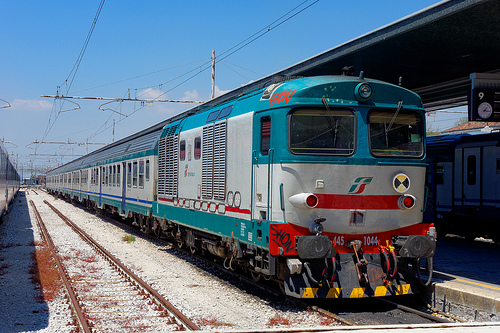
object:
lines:
[66, 45, 132, 124]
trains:
[172, 105, 413, 290]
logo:
[345, 171, 376, 206]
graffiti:
[268, 226, 302, 261]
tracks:
[38, 255, 153, 332]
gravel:
[46, 208, 72, 234]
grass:
[111, 227, 161, 262]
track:
[326, 299, 357, 325]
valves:
[382, 175, 413, 194]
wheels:
[244, 242, 270, 298]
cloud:
[16, 88, 52, 123]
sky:
[216, 26, 227, 29]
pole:
[213, 39, 215, 91]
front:
[372, 101, 424, 157]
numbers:
[327, 229, 392, 255]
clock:
[456, 65, 495, 134]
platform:
[467, 266, 498, 321]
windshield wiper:
[312, 99, 364, 151]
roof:
[251, 72, 292, 123]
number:
[474, 84, 491, 98]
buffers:
[294, 272, 442, 298]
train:
[424, 133, 498, 233]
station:
[394, 26, 474, 79]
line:
[437, 262, 493, 316]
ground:
[3, 299, 40, 322]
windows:
[282, 105, 435, 172]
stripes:
[306, 282, 314, 289]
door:
[118, 160, 130, 226]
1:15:
[483, 108, 487, 109]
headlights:
[290, 175, 435, 225]